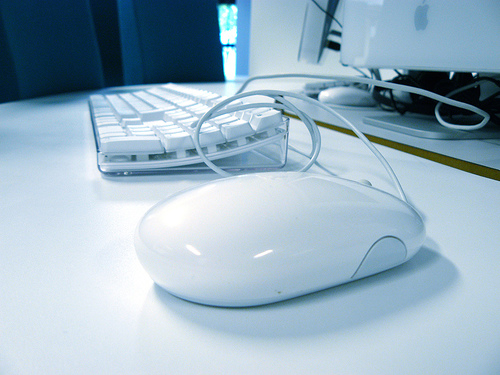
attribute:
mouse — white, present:
[117, 157, 436, 328]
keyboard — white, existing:
[76, 75, 301, 178]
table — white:
[2, 73, 499, 374]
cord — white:
[233, 69, 495, 136]